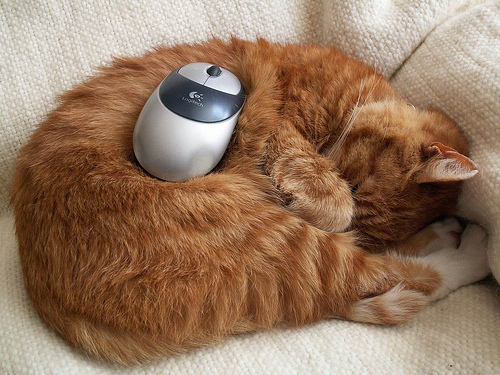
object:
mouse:
[132, 61, 249, 183]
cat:
[17, 37, 496, 369]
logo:
[182, 90, 206, 106]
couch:
[0, 1, 497, 374]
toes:
[460, 224, 487, 245]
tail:
[24, 257, 234, 369]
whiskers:
[332, 64, 383, 157]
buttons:
[178, 62, 241, 98]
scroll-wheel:
[208, 64, 221, 76]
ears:
[421, 141, 477, 183]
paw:
[280, 200, 354, 229]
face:
[340, 130, 416, 235]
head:
[324, 101, 469, 252]